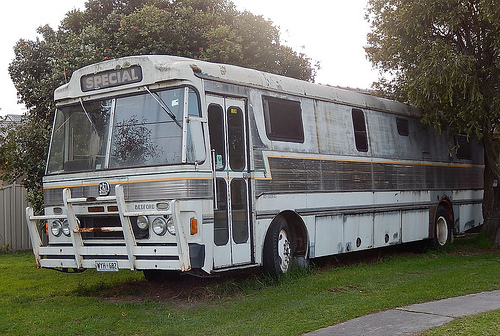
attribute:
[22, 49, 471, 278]
bus — old, told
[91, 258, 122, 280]
plate — white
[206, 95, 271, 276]
door — closed, closd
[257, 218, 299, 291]
tire — black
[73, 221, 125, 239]
bar — rusty